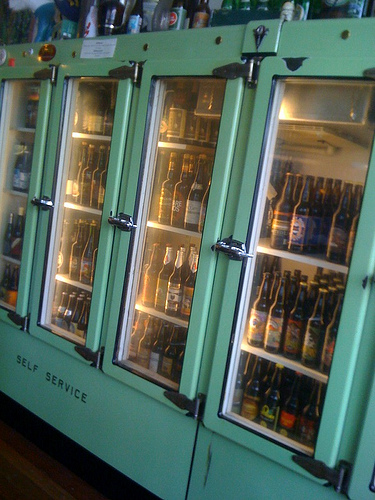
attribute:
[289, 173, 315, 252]
bottle — alcohol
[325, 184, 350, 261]
bottle — alcohol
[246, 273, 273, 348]
bottle — alcohol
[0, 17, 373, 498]
cooler — lit, metal, green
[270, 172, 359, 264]
bottles — beer, dark, brown, glass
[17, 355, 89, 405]
letters — black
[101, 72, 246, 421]
door — glass, locked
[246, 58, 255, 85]
hinge — metal, gray, black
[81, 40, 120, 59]
sticker — white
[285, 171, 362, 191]
lids — gold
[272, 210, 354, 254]
labels — blue, white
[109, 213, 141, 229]
handle — silver, metal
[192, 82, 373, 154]
unit — silver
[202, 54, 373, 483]
door — locked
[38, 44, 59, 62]
seal — gold